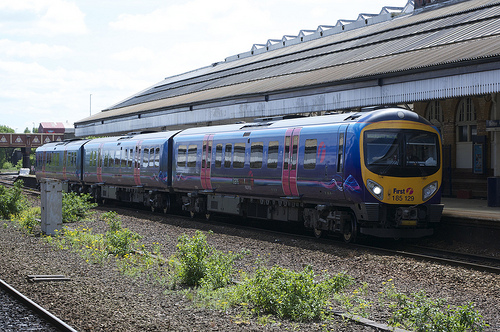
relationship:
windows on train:
[29, 130, 324, 173] [35, 108, 445, 244]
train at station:
[35, 108, 442, 236] [73, 0, 499, 245]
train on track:
[35, 108, 445, 244] [0, 175, 498, 272]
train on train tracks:
[35, 108, 445, 244] [312, 181, 494, 306]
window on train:
[281, 135, 299, 173] [35, 108, 442, 236]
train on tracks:
[35, 108, 442, 236] [3, 172, 499, 272]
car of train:
[169, 100, 445, 243] [16, 97, 433, 266]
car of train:
[81, 127, 177, 208] [16, 97, 433, 266]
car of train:
[28, 134, 85, 184] [16, 97, 433, 266]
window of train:
[224, 142, 231, 168] [35, 108, 445, 244]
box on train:
[36, 174, 64, 236] [35, 108, 442, 236]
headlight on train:
[363, 174, 394, 211] [164, 96, 457, 253]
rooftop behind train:
[41, 117, 63, 128] [35, 108, 442, 236]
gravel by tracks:
[1, 208, 382, 330] [3, 172, 499, 272]